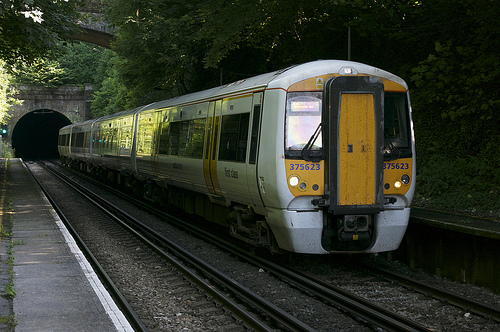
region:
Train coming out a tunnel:
[47, 43, 419, 265]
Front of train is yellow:
[274, 60, 421, 216]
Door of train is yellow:
[196, 89, 224, 200]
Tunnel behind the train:
[0, 74, 99, 171]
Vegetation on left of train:
[99, 3, 498, 91]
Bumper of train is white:
[267, 203, 413, 258]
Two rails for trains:
[24, 159, 495, 329]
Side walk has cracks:
[1, 154, 123, 330]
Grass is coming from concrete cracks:
[1, 153, 27, 325]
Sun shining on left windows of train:
[86, 97, 178, 164]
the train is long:
[50, 108, 442, 275]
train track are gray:
[68, 185, 240, 327]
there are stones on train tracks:
[100, 236, 192, 319]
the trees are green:
[83, 48, 240, 87]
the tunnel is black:
[8, 99, 105, 182]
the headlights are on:
[279, 169, 429, 210]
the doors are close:
[194, 97, 244, 220]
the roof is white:
[101, 60, 374, 101]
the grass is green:
[1, 221, 22, 330]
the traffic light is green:
[0, 123, 10, 137]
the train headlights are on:
[264, 57, 444, 289]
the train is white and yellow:
[163, 45, 455, 286]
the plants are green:
[30, 31, 150, 86]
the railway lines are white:
[35, 245, 120, 291]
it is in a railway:
[18, 85, 320, 323]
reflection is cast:
[88, 89, 250, 176]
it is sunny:
[11, 15, 350, 326]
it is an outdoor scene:
[7, 40, 409, 325]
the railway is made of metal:
[120, 191, 305, 307]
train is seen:
[160, 45, 451, 232]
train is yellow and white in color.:
[193, 81, 473, 264]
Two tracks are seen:
[106, 260, 472, 323]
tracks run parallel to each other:
[100, 207, 440, 327]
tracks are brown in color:
[191, 257, 251, 324]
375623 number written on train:
[279, 162, 327, 178]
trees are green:
[142, 23, 241, 62]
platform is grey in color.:
[13, 278, 73, 318]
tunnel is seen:
[11, 98, 116, 174]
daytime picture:
[21, 98, 499, 293]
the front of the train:
[278, 62, 420, 268]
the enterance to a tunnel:
[12, 97, 74, 162]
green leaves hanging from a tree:
[0, 7, 71, 69]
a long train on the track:
[47, 56, 406, 273]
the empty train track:
[22, 157, 253, 329]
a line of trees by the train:
[111, 0, 498, 117]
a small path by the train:
[413, 206, 498, 286]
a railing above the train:
[51, 5, 116, 45]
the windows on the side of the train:
[56, 112, 263, 183]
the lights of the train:
[286, 176, 418, 200]